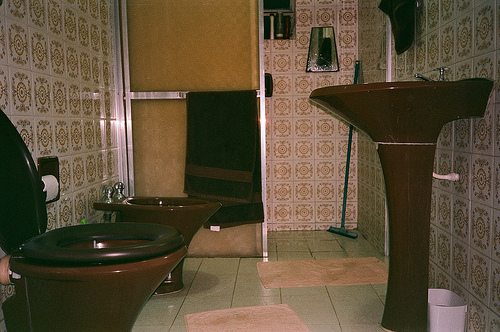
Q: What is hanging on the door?
A: Towel.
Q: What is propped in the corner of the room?
A: Broom.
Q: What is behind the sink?
A: Garbage can.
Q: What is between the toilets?
A: Toilet paper.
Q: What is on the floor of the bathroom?
A: Rugs.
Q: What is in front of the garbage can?
A: Sink.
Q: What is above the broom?
A: Mirror.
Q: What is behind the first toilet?
A: Lid.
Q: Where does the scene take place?
A: In a bathroom.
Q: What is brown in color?
A: Sink.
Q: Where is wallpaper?
A: On the walls.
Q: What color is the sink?
A: Brown.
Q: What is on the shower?
A: A towel.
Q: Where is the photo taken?
A: A bathroom.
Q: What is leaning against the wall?
A: A mop.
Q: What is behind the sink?
A: A trashcan.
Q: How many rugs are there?
A: Two.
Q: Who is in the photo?
A: No one.